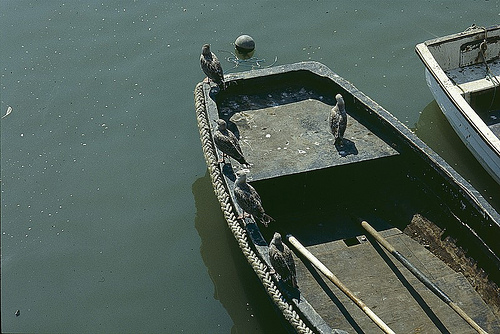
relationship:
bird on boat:
[327, 93, 349, 145] [195, 58, 500, 330]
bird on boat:
[266, 230, 300, 292] [195, 58, 500, 330]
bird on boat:
[228, 168, 277, 228] [178, 26, 483, 331]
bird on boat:
[327, 93, 349, 145] [178, 26, 483, 331]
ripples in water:
[42, 57, 142, 134] [0, 0, 500, 333]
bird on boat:
[195, 41, 229, 92] [195, 58, 500, 330]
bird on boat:
[212, 122, 247, 164] [195, 58, 500, 330]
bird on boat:
[228, 168, 277, 228] [195, 58, 500, 330]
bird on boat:
[268, 234, 303, 291] [195, 58, 500, 330]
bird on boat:
[266, 230, 300, 292] [178, 26, 483, 331]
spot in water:
[19, 132, 27, 139] [4, 4, 497, 329]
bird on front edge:
[195, 41, 229, 92] [188, 58, 319, 94]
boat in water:
[195, 58, 500, 330] [4, 4, 497, 329]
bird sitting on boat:
[327, 93, 349, 145] [195, 58, 500, 330]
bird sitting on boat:
[195, 41, 229, 92] [195, 58, 500, 330]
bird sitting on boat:
[211, 115, 253, 167] [195, 58, 500, 330]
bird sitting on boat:
[227, 173, 274, 228] [195, 58, 500, 330]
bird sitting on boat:
[266, 230, 300, 292] [195, 58, 500, 330]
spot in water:
[20, 62, 42, 85] [7, 1, 244, 288]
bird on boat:
[195, 41, 220, 93] [412, 17, 498, 156]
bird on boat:
[327, 89, 347, 146] [412, 17, 498, 156]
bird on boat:
[211, 115, 253, 167] [412, 17, 498, 156]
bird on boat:
[228, 168, 277, 228] [412, 17, 498, 156]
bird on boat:
[266, 230, 300, 292] [412, 17, 498, 156]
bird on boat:
[211, 115, 253, 167] [195, 58, 500, 330]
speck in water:
[369, 53, 376, 60] [42, 48, 169, 259]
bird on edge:
[195, 41, 229, 92] [211, 175, 255, 252]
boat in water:
[418, 23, 499, 182] [4, 4, 497, 329]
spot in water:
[51, 203, 72, 213] [4, 4, 497, 329]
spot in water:
[13, 116, 34, 141] [4, 4, 497, 329]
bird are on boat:
[195, 41, 229, 92] [195, 58, 500, 330]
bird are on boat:
[327, 93, 349, 145] [195, 58, 500, 330]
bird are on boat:
[211, 115, 253, 167] [195, 58, 500, 330]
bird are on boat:
[228, 168, 277, 228] [195, 58, 500, 330]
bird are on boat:
[266, 230, 300, 292] [195, 58, 500, 330]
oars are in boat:
[187, 30, 358, 297] [220, 45, 390, 245]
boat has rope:
[195, 58, 500, 330] [191, 82, 313, 332]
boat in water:
[171, 36, 461, 332] [191, 55, 496, 325]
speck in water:
[5, 94, 19, 121] [15, 17, 450, 310]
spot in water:
[56, 91, 129, 145] [37, 194, 181, 255]